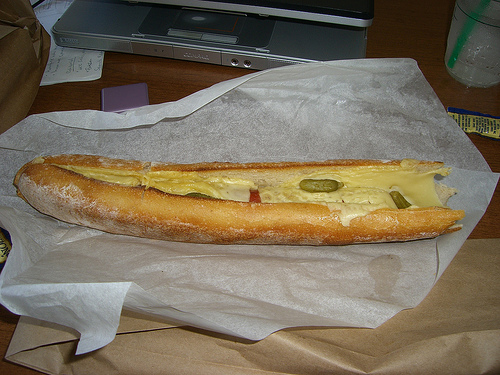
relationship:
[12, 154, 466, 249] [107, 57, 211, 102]
baguette on table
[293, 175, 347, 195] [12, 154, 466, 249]
jalapeno on baguette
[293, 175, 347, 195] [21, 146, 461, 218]
jalapeno in sandwiches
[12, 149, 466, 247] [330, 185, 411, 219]
baguette with egg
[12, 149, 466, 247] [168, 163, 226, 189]
baguette with cheese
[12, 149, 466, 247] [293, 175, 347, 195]
baguette with jalapeno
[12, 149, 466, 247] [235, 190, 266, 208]
baguette with bell pepper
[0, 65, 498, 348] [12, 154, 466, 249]
wax paper under baguette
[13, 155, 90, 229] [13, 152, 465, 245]
end of a sandwhich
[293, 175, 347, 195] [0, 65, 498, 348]
jalapeno of wax paper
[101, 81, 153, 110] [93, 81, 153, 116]
piece of piece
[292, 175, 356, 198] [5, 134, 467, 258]
jalapeno in sandwich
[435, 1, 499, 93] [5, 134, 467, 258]
beverage by sandwich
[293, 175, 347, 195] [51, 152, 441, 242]
jalapeno in sandwich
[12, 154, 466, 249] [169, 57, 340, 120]
baguette on paper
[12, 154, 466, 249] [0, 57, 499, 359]
baguette on wax paper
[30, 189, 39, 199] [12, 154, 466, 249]
flour on baguette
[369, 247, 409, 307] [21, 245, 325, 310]
stain on paper